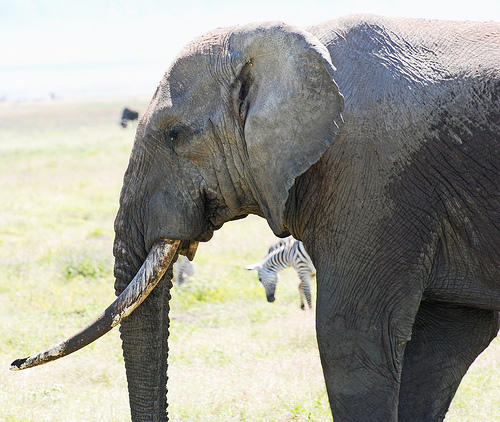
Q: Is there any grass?
A: Yes, there is grass.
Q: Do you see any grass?
A: Yes, there is grass.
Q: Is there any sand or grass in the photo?
A: Yes, there is grass.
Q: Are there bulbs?
A: No, there are no bulbs.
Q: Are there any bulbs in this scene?
A: No, there are no bulbs.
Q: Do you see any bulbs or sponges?
A: No, there are no bulbs or sponges.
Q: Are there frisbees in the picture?
A: No, there are no frisbees.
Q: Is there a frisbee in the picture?
A: No, there are no frisbees.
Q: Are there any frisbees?
A: No, there are no frisbees.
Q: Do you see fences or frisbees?
A: No, there are no frisbees or fences.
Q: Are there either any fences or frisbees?
A: No, there are no frisbees or fences.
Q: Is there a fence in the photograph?
A: No, there are no fences.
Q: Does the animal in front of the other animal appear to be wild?
A: Yes, the animal is wild.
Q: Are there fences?
A: No, there are no fences.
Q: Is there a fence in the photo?
A: No, there are no fences.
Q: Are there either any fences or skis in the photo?
A: No, there are no fences or skis.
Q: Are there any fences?
A: No, there are no fences.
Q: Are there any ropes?
A: No, there are no ropes.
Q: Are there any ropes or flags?
A: No, there are no ropes or flags.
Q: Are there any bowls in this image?
A: No, there are no bowls.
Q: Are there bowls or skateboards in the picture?
A: No, there are no bowls or skateboards.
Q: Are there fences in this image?
A: No, there are no fences.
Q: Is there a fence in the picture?
A: No, there are no fences.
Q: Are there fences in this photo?
A: No, there are no fences.